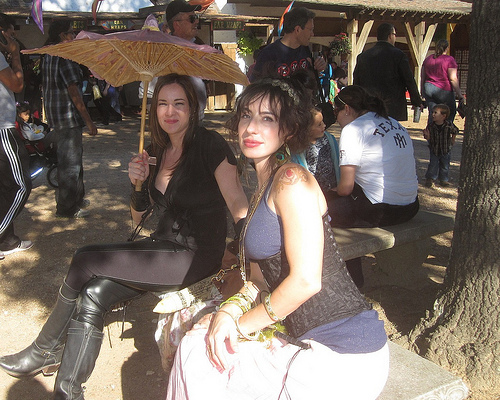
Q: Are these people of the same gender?
A: No, they are both male and female.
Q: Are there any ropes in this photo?
A: No, there are no ropes.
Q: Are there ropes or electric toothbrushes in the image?
A: No, there are no ropes or electric toothbrushes.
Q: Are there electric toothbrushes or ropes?
A: No, there are no ropes or electric toothbrushes.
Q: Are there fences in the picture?
A: No, there are no fences.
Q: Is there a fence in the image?
A: No, there are no fences.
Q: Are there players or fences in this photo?
A: No, there are no fences or players.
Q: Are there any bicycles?
A: No, there are no bicycles.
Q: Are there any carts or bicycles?
A: No, there are no bicycles or carts.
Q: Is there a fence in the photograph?
A: No, there are no fences.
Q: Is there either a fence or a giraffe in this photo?
A: No, there are no fences or giraffes.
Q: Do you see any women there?
A: Yes, there is a woman.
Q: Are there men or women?
A: Yes, there is a woman.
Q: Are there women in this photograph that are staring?
A: Yes, there is a woman that is staring.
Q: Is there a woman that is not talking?
A: Yes, there is a woman that is staring.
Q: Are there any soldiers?
A: No, there are no soldiers.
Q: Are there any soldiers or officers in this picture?
A: No, there are no soldiers or officers.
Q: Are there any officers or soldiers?
A: No, there are no soldiers or officers.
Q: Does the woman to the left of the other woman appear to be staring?
A: Yes, the woman is staring.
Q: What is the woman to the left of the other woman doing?
A: The woman is staring.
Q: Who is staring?
A: The woman is staring.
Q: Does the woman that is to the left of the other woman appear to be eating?
A: No, the woman is staring.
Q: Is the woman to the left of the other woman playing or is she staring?
A: The woman is staring.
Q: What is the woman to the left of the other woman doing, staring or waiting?
A: The woman is staring.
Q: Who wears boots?
A: The woman wears boots.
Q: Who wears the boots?
A: The woman wears boots.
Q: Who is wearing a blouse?
A: The woman is wearing a blouse.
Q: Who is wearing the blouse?
A: The woman is wearing a blouse.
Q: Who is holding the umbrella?
A: The woman is holding the umbrella.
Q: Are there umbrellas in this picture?
A: Yes, there is an umbrella.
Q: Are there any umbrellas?
A: Yes, there is an umbrella.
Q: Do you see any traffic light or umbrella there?
A: Yes, there is an umbrella.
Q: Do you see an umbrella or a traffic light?
A: Yes, there is an umbrella.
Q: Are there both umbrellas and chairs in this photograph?
A: No, there is an umbrella but no chairs.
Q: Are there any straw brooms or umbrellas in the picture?
A: Yes, there is a straw umbrella.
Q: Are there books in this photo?
A: No, there are no books.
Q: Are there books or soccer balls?
A: No, there are no books or soccer balls.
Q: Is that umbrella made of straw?
A: Yes, the umbrella is made of straw.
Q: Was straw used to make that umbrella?
A: Yes, the umbrella is made of straw.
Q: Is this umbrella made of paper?
A: No, the umbrella is made of straw.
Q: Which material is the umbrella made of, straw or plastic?
A: The umbrella is made of straw.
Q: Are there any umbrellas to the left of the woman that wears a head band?
A: Yes, there is an umbrella to the left of the woman.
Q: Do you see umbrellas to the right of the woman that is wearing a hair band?
A: No, the umbrella is to the left of the woman.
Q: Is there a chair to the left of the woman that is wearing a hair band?
A: No, there is an umbrella to the left of the woman.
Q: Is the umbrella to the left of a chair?
A: No, the umbrella is to the left of the woman.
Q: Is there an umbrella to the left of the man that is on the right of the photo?
A: Yes, there is an umbrella to the left of the man.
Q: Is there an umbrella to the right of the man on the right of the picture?
A: No, the umbrella is to the left of the man.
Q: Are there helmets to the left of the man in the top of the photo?
A: No, there is an umbrella to the left of the man.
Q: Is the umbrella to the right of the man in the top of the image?
A: No, the umbrella is to the left of the man.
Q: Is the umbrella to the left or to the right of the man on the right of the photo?
A: The umbrella is to the left of the man.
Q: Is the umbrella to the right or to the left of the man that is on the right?
A: The umbrella is to the left of the man.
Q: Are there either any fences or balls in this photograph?
A: No, there are no fences or balls.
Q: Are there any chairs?
A: No, there are no chairs.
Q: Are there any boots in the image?
A: Yes, there are boots.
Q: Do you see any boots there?
A: Yes, there are boots.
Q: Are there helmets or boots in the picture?
A: Yes, there are boots.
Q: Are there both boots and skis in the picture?
A: No, there are boots but no skis.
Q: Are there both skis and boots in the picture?
A: No, there are boots but no skis.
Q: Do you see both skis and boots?
A: No, there are boots but no skis.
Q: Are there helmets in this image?
A: No, there are no helmets.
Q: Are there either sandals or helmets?
A: No, there are no helmets or sandals.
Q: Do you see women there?
A: Yes, there is a woman.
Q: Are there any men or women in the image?
A: Yes, there is a woman.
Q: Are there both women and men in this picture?
A: Yes, there are both a woman and a man.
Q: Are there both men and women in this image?
A: Yes, there are both a woman and a man.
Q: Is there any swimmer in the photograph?
A: No, there are no swimmers.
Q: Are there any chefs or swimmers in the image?
A: No, there are no swimmers or chefs.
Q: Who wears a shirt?
A: The woman wears a shirt.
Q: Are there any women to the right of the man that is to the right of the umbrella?
A: Yes, there is a woman to the right of the man.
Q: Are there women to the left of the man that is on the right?
A: No, the woman is to the right of the man.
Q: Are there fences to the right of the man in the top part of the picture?
A: No, there is a woman to the right of the man.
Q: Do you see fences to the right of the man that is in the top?
A: No, there is a woman to the right of the man.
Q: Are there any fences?
A: No, there are no fences.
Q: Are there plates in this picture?
A: No, there are no plates.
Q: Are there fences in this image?
A: No, there are no fences.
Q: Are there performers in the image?
A: No, there are no performers.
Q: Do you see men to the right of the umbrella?
A: Yes, there is a man to the right of the umbrella.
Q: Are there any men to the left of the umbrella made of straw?
A: No, the man is to the right of the umbrella.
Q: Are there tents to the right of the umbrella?
A: No, there is a man to the right of the umbrella.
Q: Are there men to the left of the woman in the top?
A: Yes, there is a man to the left of the woman.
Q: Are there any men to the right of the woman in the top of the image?
A: No, the man is to the left of the woman.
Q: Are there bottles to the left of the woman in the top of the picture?
A: No, there is a man to the left of the woman.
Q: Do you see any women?
A: Yes, there is a woman.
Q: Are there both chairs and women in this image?
A: No, there is a woman but no chairs.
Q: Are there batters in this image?
A: No, there are no batters.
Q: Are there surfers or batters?
A: No, there are no batters or surfers.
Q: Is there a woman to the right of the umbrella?
A: Yes, there is a woman to the right of the umbrella.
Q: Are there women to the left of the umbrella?
A: No, the woman is to the right of the umbrella.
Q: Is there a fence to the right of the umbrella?
A: No, there is a woman to the right of the umbrella.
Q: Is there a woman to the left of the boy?
A: Yes, there is a woman to the left of the boy.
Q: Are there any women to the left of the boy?
A: Yes, there is a woman to the left of the boy.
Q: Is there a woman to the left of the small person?
A: Yes, there is a woman to the left of the boy.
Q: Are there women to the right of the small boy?
A: No, the woman is to the left of the boy.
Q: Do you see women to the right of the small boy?
A: No, the woman is to the left of the boy.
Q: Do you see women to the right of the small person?
A: No, the woman is to the left of the boy.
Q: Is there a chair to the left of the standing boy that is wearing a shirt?
A: No, there is a woman to the left of the boy.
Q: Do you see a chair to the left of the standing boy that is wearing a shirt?
A: No, there is a woman to the left of the boy.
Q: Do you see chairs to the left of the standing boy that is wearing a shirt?
A: No, there is a woman to the left of the boy.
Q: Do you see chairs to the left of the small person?
A: No, there is a woman to the left of the boy.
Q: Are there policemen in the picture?
A: No, there are no policemen.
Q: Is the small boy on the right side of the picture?
A: Yes, the boy is on the right of the image.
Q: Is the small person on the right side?
A: Yes, the boy is on the right of the image.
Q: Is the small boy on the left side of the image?
A: No, the boy is on the right of the image.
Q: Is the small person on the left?
A: No, the boy is on the right of the image.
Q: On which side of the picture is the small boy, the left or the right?
A: The boy is on the right of the image.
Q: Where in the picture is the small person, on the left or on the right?
A: The boy is on the right of the image.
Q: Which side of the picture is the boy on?
A: The boy is on the right of the image.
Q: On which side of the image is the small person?
A: The boy is on the right of the image.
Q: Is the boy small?
A: Yes, the boy is small.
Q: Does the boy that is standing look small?
A: Yes, the boy is small.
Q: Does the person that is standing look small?
A: Yes, the boy is small.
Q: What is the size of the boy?
A: The boy is small.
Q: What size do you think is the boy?
A: The boy is small.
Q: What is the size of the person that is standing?
A: The boy is small.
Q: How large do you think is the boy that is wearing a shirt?
A: The boy is small.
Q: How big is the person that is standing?
A: The boy is small.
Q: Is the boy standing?
A: Yes, the boy is standing.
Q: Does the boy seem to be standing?
A: Yes, the boy is standing.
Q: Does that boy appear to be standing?
A: Yes, the boy is standing.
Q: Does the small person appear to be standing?
A: Yes, the boy is standing.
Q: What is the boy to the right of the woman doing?
A: The boy is standing.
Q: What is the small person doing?
A: The boy is standing.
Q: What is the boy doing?
A: The boy is standing.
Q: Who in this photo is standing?
A: The boy is standing.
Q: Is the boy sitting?
A: No, the boy is standing.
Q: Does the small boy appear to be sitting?
A: No, the boy is standing.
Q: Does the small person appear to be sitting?
A: No, the boy is standing.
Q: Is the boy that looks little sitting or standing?
A: The boy is standing.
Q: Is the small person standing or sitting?
A: The boy is standing.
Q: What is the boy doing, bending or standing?
A: The boy is standing.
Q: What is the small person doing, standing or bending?
A: The boy is standing.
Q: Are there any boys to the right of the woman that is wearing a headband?
A: Yes, there is a boy to the right of the woman.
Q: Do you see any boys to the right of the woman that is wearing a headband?
A: Yes, there is a boy to the right of the woman.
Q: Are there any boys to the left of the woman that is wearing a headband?
A: No, the boy is to the right of the woman.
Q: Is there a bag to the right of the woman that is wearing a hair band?
A: No, there is a boy to the right of the woman.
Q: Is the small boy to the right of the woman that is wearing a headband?
A: Yes, the boy is to the right of the woman.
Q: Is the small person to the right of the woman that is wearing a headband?
A: Yes, the boy is to the right of the woman.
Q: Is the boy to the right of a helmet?
A: No, the boy is to the right of the woman.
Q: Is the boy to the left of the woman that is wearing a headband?
A: No, the boy is to the right of the woman.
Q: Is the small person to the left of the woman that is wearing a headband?
A: No, the boy is to the right of the woman.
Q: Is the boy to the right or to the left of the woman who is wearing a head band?
A: The boy is to the right of the woman.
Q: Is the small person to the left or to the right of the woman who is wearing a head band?
A: The boy is to the right of the woman.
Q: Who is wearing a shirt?
A: The boy is wearing a shirt.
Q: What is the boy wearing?
A: The boy is wearing a shirt.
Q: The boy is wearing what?
A: The boy is wearing a shirt.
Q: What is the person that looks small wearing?
A: The boy is wearing a shirt.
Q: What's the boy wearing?
A: The boy is wearing a shirt.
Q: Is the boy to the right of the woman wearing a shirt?
A: Yes, the boy is wearing a shirt.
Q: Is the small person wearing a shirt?
A: Yes, the boy is wearing a shirt.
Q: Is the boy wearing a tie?
A: No, the boy is wearing a shirt.